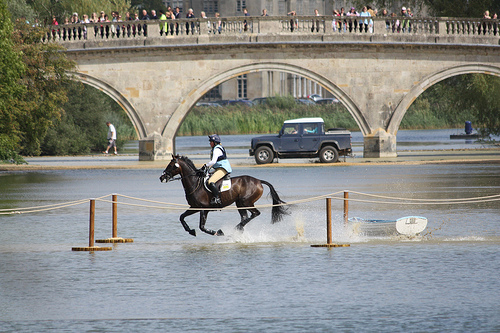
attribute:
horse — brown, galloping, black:
[168, 153, 291, 235]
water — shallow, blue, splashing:
[2, 166, 492, 327]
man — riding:
[200, 133, 234, 200]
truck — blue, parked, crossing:
[251, 118, 355, 162]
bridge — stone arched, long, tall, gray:
[13, 12, 496, 160]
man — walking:
[105, 121, 120, 151]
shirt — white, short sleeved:
[110, 127, 116, 137]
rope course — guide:
[4, 193, 497, 250]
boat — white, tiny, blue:
[349, 211, 424, 235]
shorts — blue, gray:
[107, 137, 116, 145]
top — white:
[280, 114, 324, 124]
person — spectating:
[397, 7, 416, 37]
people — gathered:
[6, 9, 499, 31]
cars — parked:
[194, 93, 346, 105]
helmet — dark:
[208, 131, 221, 145]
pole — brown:
[317, 193, 346, 250]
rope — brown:
[3, 195, 499, 211]